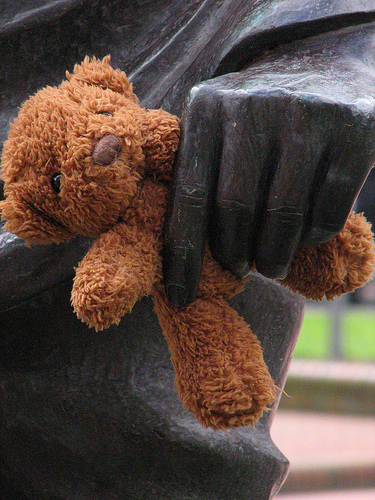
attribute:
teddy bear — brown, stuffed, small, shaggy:
[1, 57, 374, 430]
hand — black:
[155, 30, 369, 305]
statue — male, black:
[1, 2, 374, 495]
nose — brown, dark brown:
[87, 133, 124, 168]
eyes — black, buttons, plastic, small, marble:
[45, 107, 113, 193]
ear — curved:
[67, 53, 147, 99]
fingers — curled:
[213, 121, 371, 276]